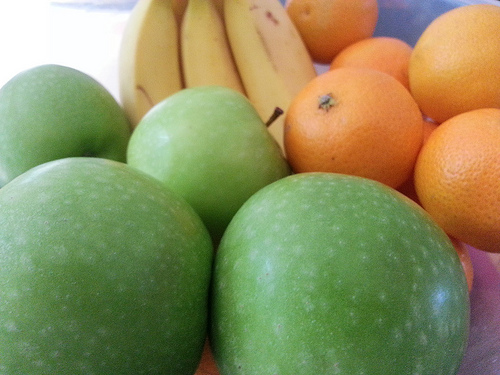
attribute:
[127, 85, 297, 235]
apple — large, green, clean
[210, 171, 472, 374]
apple — green, clean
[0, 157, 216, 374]
apple — green, clean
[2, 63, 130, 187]
apple — green, clean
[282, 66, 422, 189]
orange — large, round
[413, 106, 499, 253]
orange — large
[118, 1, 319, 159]
bananas — yellow, in a group, ripe, long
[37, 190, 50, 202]
spot — white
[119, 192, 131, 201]
spot — white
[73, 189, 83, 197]
spot — white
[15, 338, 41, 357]
spot — white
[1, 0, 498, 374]
fruit — plentiful, handful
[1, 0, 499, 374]
surface — purple, bright